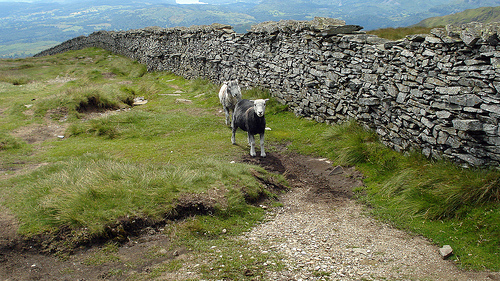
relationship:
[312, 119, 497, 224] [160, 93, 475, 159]
grass growing at base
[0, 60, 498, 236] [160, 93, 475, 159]
grass growing at base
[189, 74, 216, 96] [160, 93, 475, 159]
grass growing at base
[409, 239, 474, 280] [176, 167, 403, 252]
rock on ground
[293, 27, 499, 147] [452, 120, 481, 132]
wall contains rock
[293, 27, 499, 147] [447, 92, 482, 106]
wall contains rock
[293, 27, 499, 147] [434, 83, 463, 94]
wall contains rock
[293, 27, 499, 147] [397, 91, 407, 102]
wall contains rock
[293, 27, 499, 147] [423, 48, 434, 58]
wall contains rock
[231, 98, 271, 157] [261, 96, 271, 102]
goat has left horn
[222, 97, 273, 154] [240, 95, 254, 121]
goat has horn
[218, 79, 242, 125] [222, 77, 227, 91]
goat has horn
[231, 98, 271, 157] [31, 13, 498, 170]
goat stands near wall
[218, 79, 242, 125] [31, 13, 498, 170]
goat stands near wall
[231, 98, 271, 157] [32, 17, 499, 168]
goat stands near fence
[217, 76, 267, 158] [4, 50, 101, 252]
sheep stands on grass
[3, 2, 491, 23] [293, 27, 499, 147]
hills behind wall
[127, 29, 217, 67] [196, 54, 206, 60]
fence contains stone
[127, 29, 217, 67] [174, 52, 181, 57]
fence contains stone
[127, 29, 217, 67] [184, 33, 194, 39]
fence contains stone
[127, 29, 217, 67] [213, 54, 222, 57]
fence contains stone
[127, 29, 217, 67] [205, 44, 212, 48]
fence contains stone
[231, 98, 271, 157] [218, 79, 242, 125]
goat in front of goat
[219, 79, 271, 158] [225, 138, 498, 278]
sheep following path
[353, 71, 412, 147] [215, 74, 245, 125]
wall near goat